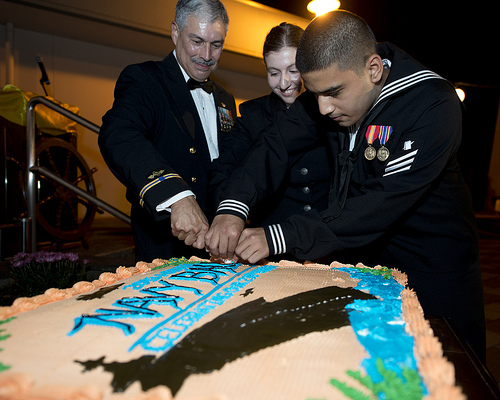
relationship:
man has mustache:
[93, 1, 238, 266] [187, 55, 216, 67]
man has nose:
[93, 1, 238, 266] [199, 42, 217, 61]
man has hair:
[93, 1, 238, 266] [170, 0, 232, 33]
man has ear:
[93, 1, 238, 266] [169, 19, 184, 47]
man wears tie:
[93, 1, 238, 266] [180, 76, 224, 97]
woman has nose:
[235, 18, 339, 262] [277, 71, 295, 93]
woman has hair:
[235, 18, 339, 262] [258, 18, 315, 80]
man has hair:
[207, 5, 491, 369] [291, 9, 379, 76]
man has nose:
[207, 5, 491, 369] [314, 97, 338, 117]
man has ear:
[207, 5, 491, 369] [362, 49, 386, 88]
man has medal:
[207, 5, 491, 369] [359, 121, 378, 163]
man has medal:
[207, 5, 491, 369] [377, 123, 392, 165]